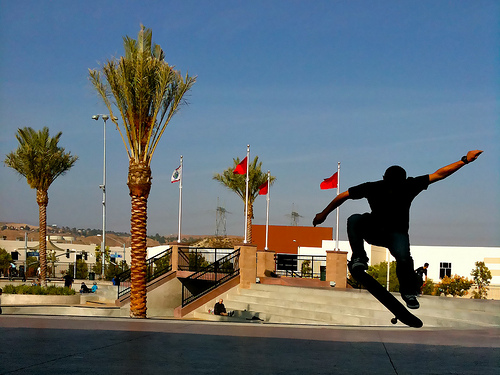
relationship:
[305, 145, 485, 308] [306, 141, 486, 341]
skateboarder doing a trick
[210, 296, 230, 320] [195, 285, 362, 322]
man sitting on step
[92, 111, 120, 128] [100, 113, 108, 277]
lights attached to pole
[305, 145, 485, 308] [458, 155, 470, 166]
skateboarder wearing watch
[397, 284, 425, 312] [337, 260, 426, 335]
foot not on board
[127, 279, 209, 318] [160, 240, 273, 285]
walkway under passage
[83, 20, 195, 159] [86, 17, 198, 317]
leaves on top palm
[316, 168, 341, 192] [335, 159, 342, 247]
flag on top of pole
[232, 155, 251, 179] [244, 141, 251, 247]
flag on top of pole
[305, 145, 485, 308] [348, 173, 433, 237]
skateboarder wearing black shirt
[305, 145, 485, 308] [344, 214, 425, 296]
skateboarder wearing dark pants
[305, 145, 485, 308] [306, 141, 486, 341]
skateboarder doing trick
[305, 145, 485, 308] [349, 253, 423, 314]
skateboarder wearing shoes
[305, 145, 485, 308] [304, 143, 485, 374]
skateboarder performing a jump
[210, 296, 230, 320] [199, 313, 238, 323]
man on cement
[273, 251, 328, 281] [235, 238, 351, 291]
railings surrounding entryway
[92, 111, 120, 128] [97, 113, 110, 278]
lights on tall pole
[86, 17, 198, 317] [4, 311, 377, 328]
tree by sidewalk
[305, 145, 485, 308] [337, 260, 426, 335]
skateboarder jumps on skateboard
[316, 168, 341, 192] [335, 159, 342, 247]
flag on a pole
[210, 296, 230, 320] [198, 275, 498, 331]
man sitting on stairs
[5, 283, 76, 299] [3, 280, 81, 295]
bushes in a group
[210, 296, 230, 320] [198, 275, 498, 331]
people sitting on stair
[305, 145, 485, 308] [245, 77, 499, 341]
skateboarder in air